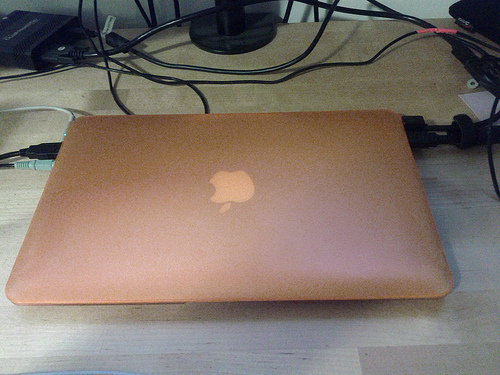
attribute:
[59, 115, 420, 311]
laptop — closed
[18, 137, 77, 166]
usb cable — black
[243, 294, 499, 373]
table — wooden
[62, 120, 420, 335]
laptop — rose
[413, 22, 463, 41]
sticker — red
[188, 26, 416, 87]
cord — black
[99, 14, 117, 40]
tag — white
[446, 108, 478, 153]
strap — Velco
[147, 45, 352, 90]
cords — black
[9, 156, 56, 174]
plug — green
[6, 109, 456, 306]
laptop — gold, rectangular , pink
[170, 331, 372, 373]
wood — white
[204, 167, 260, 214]
logo — apple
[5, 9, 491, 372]
table — Wood 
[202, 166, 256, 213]
logo — apple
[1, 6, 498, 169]
cables — black 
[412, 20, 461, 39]
tape — red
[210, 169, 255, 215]
logo — apple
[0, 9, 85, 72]
box — black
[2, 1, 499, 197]
wires — black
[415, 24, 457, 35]
seal — pink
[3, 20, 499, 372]
cloth — white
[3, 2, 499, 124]
wires — black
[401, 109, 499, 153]
plugs — bulky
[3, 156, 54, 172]
plug — green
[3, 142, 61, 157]
plug — black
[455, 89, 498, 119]
paper — white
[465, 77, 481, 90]
button — white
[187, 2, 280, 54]
stand — black